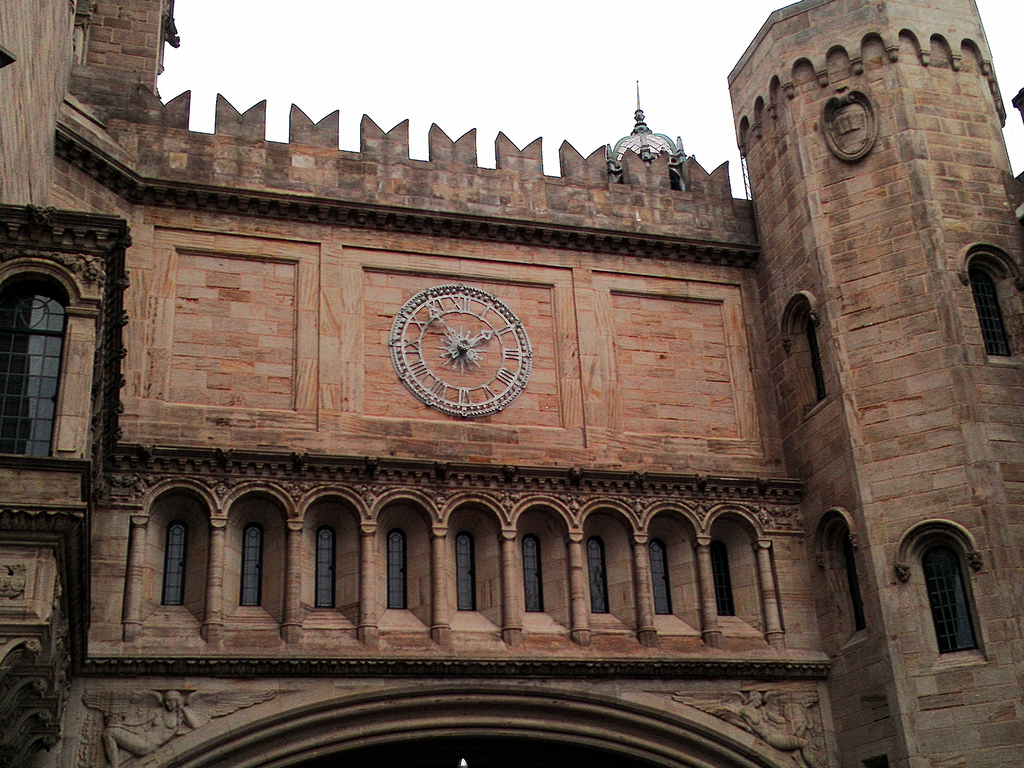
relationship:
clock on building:
[388, 282, 535, 418] [4, 4, 1022, 763]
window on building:
[709, 538, 738, 616] [4, 4, 1022, 763]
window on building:
[647, 536, 672, 614] [4, 4, 1022, 763]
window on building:
[520, 526, 544, 613] [4, 4, 1022, 763]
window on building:
[388, 528, 408, 610] [4, 4, 1022, 763]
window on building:
[233, 513, 275, 607] [4, 4, 1022, 763]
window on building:
[158, 510, 193, 597] [4, 4, 1022, 763]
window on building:
[239, 522, 266, 607] [4, 4, 1022, 763]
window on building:
[455, 531, 477, 613] [4, 4, 1022, 763]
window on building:
[639, 526, 676, 615] [4, 4, 1022, 763]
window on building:
[583, 526, 605, 607] [4, 4, 1022, 763]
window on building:
[447, 532, 476, 610] [4, 4, 1022, 763]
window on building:
[586, 535, 610, 614] [4, 4, 1022, 763]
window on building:
[376, 515, 411, 608] [4, 4, 1022, 763]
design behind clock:
[345, 243, 588, 460] [388, 282, 535, 418]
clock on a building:
[346, 216, 599, 448] [4, 4, 1022, 763]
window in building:
[239, 522, 266, 607] [4, 4, 1022, 763]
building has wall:
[4, 4, 1022, 763] [142, 240, 775, 735]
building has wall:
[4, 4, 1022, 763] [139, 246, 781, 469]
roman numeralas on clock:
[483, 354, 514, 415] [386, 275, 538, 433]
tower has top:
[726, 1, 1022, 767] [716, 4, 1010, 121]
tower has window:
[726, 1, 1022, 767] [883, 510, 1000, 671]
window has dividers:
[3, 253, 83, 472] [4, 290, 63, 450]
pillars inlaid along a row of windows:
[113, 465, 798, 649] [150, 512, 758, 614]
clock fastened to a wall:
[388, 282, 535, 418] [93, 132, 830, 727]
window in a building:
[521, 532, 545, 612] [4, 4, 1022, 763]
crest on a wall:
[811, 81, 885, 170] [772, 13, 971, 735]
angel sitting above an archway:
[668, 681, 839, 748] [130, 701, 768, 753]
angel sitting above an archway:
[76, 677, 284, 751] [130, 701, 768, 753]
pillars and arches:
[201, 506, 234, 630] [504, 498, 578, 535]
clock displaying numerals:
[388, 282, 535, 418] [402, 290, 523, 401]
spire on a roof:
[629, 70, 649, 127] [608, 132, 686, 174]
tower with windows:
[731, 11, 993, 752] [899, 510, 990, 671]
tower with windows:
[731, 11, 993, 752] [806, 498, 882, 646]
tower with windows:
[731, 11, 993, 752] [943, 238, 989, 366]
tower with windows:
[731, 11, 993, 752] [770, 281, 840, 424]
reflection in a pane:
[947, 577, 982, 649] [923, 556, 984, 654]